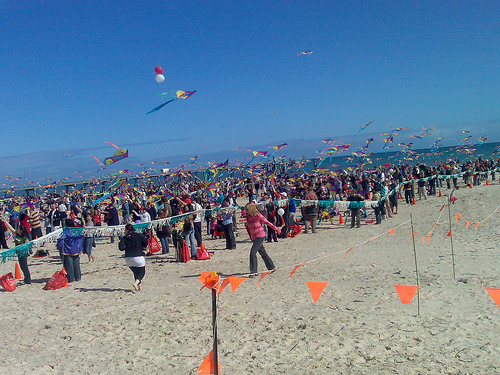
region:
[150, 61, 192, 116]
kites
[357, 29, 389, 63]
white clouds in blue sky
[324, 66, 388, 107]
white clouds in blue sky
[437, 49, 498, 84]
white clouds in blue sky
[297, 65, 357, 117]
white clouds in blue sky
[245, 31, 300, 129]
white clouds in blue sky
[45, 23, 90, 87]
white clouds in blue sky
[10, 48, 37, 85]
white clouds in blue sky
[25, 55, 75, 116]
white clouds in blue sky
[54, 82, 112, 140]
white clouds in blue sky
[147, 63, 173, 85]
Colorful high flying kite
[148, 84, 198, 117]
Colorful high flying kite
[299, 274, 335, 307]
Designation flag for area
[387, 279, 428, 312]
Designation flag for area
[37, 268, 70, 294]
Designation flag for area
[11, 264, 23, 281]
Orange traffic pattern cone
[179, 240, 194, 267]
Orange traffic pattern cone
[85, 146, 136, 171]
Colorful high flying kite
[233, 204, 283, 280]
Happy kite flying participant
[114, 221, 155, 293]
Energetic kite flying participant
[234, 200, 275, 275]
person on the beach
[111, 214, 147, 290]
tree along the side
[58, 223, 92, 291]
tree along the side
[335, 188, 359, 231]
tree along the side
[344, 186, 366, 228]
tree along the side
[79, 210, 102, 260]
tree along the side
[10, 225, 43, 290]
tree along the side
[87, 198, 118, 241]
tree along the side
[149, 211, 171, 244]
tree along the side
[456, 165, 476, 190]
tree along the side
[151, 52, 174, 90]
red and white balloon in sky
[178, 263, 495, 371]
orange flags on posts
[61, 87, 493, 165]
kites flying in the air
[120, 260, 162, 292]
woman's pants are black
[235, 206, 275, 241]
woman's shirt is pink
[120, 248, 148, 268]
woman's undershirt is white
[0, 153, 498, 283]
people standing in a crowd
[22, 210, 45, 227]
person's shirt is striped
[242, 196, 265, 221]
woman's hair is blonde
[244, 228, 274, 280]
woman's pants are gray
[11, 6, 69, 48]
white clouds n blue sky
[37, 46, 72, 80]
white clouds n blue sky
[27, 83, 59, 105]
white clouds n blue sky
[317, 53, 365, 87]
white clouds n blue sky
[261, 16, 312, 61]
white clouds n blue sky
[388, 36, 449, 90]
white clouds n blue sky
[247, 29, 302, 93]
white clouds n blue sky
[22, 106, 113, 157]
white clouds n blue sky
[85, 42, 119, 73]
white clouds n blue sky